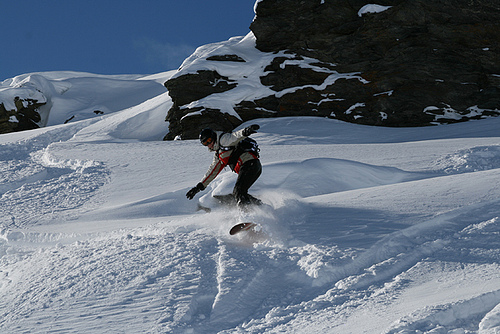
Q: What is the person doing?
A: Snowboarding.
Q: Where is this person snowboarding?
A: On ski slope.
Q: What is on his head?
A: A helmet.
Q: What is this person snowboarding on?
A: Snow.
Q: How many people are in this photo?
A: One person.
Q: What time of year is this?
A: Winter.